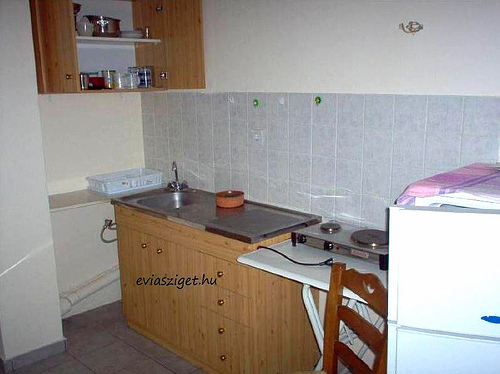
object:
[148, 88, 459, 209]
backsplash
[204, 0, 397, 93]
wall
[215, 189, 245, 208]
bowl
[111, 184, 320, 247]
counter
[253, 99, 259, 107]
magnets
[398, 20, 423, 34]
hook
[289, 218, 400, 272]
burner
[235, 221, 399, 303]
table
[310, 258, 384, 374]
chair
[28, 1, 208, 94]
cabinet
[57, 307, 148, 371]
tile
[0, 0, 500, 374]
kitchen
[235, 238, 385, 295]
counter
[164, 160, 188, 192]
faucet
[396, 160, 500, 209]
cloth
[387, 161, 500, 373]
refrigerator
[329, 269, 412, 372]
back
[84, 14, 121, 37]
pot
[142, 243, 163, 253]
drawer pulls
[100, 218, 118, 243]
piping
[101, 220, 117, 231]
valves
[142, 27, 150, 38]
glasses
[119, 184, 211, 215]
sink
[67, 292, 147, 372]
floor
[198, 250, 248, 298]
drawers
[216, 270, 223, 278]
handle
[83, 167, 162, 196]
basket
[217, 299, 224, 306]
knobs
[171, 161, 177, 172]
spout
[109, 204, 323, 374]
cabinets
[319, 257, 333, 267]
plug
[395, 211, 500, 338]
door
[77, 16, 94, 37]
containers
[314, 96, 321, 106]
circle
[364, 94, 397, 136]
tile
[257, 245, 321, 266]
cord